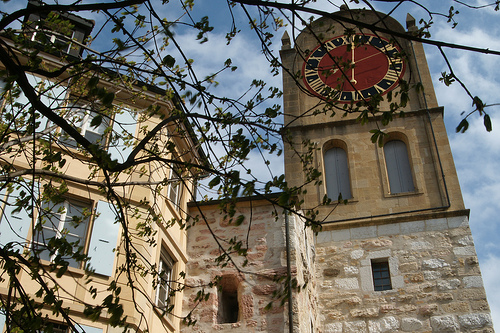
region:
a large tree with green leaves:
[0, 0, 499, 332]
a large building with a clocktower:
[0, 0, 495, 332]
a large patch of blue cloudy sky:
[0, 0, 498, 332]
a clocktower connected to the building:
[278, 3, 494, 331]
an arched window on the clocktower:
[375, 126, 425, 196]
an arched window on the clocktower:
[315, 133, 360, 204]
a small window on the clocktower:
[370, 256, 392, 291]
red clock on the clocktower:
[301, 32, 406, 104]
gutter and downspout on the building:
[187, 190, 294, 332]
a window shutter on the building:
[83, 200, 121, 276]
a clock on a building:
[223, 8, 496, 308]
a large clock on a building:
[278, 23, 463, 226]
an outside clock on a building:
[264, 26, 482, 206]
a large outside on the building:
[237, 6, 478, 176]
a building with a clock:
[272, 16, 488, 224]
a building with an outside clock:
[257, 15, 499, 190]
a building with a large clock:
[271, 13, 479, 248]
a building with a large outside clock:
[271, 9, 487, 197]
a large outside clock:
[251, 18, 498, 240]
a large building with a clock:
[240, 16, 492, 318]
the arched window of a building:
[320, 138, 355, 209]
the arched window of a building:
[377, 131, 422, 205]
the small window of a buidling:
[216, 271, 238, 320]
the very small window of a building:
[369, 250, 391, 292]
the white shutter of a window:
[88, 196, 125, 278]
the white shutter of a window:
[2, 177, 39, 257]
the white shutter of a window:
[10, 73, 37, 133]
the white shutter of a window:
[35, 75, 65, 142]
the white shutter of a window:
[107, 106, 137, 165]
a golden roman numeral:
[350, 88, 365, 106]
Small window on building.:
[355, 245, 395, 297]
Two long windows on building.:
[305, 129, 423, 203]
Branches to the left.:
[0, 12, 165, 326]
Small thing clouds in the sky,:
[184, 21, 268, 76]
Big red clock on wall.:
[305, 13, 429, 120]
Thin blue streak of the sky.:
[437, 8, 494, 35]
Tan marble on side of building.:
[318, 199, 449, 216]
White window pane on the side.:
[88, 195, 125, 299]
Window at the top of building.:
[22, 5, 84, 55]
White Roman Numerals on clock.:
[302, 45, 342, 103]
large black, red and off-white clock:
[301, 30, 405, 104]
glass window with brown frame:
[370, 257, 392, 290]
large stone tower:
[279, 5, 491, 332]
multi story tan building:
[1, 3, 210, 332]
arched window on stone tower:
[381, 137, 418, 195]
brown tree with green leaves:
[1, 0, 498, 331]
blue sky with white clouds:
[2, 0, 498, 330]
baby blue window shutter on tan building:
[83, 198, 120, 277]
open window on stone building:
[214, 273, 241, 325]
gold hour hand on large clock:
[348, 43, 357, 83]